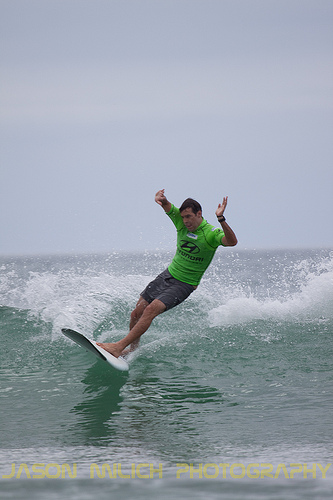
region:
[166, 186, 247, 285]
green rash guard on man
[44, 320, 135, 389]
white surf board on wave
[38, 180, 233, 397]
man riding white surf board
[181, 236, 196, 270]
black writing on front of board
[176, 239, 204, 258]
black logo on board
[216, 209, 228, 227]
black watch on board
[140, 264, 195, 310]
tan shorts on man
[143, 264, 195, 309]
tan board shorts on man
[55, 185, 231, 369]
man riding on wave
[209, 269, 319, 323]
white water from wave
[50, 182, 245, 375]
surfer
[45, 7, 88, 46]
white clouds in blue sky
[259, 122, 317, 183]
white clouds in blue sky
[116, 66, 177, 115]
white clouds in blue sky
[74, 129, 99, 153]
white clouds in blue sky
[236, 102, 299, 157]
white clouds in blue sky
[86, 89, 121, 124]
white clouds in blue sky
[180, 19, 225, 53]
white clouds in blue sky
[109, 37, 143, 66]
white clouds in blue sky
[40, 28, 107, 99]
white clouds in blue sky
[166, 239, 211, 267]
the black hundai logo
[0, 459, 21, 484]
the yellow letter J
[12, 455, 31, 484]
the yellow letter A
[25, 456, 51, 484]
the yellow letter S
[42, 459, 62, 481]
the yellow letter O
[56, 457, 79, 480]
the yellow letter N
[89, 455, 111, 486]
the yellow letter M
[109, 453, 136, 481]
the yellow letter L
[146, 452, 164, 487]
the yellow letter H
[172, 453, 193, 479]
the yellow letter P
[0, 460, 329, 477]
a watermark that says JASON MILICH PHOTOGRAPHY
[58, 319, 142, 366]
a surfboard in the water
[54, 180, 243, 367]
a man riding a white surfboard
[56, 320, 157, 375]
a white surfboard in the water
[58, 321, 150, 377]
a white surfboard riding a wave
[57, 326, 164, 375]
a white surfboard getting hit by a wave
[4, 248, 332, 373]
a large wave behind a man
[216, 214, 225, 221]
a man wearing a wristband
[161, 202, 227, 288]
a man wearing a green shirt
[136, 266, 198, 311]
a man wearing black shorts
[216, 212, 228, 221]
black watch on wrist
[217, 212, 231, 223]
watch on wrist of man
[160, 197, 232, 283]
man wearing a green rash guard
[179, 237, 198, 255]
black logo on front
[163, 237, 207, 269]
black writing on rash guard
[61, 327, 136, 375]
white surf board on a wave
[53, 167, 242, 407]
man riding board on wave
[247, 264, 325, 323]
white water from breaking wave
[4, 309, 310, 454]
large wave in ocean